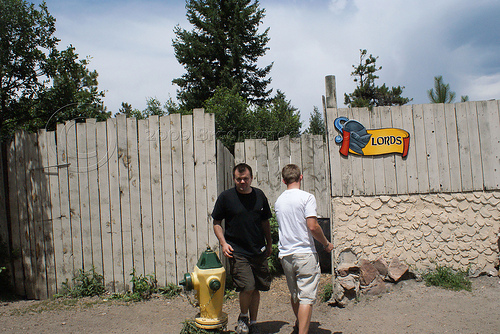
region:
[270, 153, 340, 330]
man with white tee shirt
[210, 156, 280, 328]
man wearing black shirt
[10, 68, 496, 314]
fence behind two men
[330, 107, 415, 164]
a sign on a fence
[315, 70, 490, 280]
a fence on a wall of concret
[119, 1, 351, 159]
tree behind a fence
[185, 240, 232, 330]
A yellow and green fire hydrant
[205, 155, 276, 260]
Man wearing a black shirt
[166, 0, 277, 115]
A tall green tree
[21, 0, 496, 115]
White clouds in the sky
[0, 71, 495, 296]
The fence is made of wood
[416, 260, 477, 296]
A green patch of grass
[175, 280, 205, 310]
Chain on a fire hydrant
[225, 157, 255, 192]
Brown hair on man's head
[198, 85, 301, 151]
Green leaves on a tree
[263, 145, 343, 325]
this is a man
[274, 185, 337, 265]
man wearing a white shirt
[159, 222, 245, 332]
a multicolored fire hydrant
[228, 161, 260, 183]
man has dark hair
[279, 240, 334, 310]
man wearing khaki shorts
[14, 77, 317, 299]
a wooden fence in background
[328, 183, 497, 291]
a low stone wall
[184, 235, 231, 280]
green top on fire hydrant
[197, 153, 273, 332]
man wearing black shirt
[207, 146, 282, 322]
man wearing brown shorts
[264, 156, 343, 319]
man wearing a white t-shirt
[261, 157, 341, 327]
man wearing tan pants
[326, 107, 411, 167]
yellow sign on the gate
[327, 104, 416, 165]
sign with knight on it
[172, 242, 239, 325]
yellow and green fire hydrant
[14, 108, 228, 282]
light tan wood gate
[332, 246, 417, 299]
rocks in the dirt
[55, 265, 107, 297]
small bush by the gate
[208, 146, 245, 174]
man has brown hair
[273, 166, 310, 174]
man has blond hair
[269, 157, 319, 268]
man has white shirt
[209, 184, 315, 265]
man has black shirt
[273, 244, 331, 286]
man has grey shorts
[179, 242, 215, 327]
yellow and green hydrant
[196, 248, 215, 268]
green cap on hydrant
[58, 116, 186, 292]
grey fence behind boys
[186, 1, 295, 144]
tall and green pine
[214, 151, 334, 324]
Two men near the hydrant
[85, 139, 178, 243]
A wooden fence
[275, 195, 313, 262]
White t-shirt in the photo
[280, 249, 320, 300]
Gray shorts in the photo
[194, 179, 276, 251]
man wearing a black shirt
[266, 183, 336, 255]
man wearing a white shirt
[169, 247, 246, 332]
a yellow and green fire hydrant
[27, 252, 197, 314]
weeds on the ground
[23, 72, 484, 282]
a brown tall fence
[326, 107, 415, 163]
a yellow and blue sign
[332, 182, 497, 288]
a stone tan wall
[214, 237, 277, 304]
brown pair of shorts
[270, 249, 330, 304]
khaki pair of shorts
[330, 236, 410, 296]
broken part of wall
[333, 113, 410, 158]
sign is on wooden wall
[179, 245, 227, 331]
fire hydrant is yellow and green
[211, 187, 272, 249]
shirt is black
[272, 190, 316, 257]
shirt is white